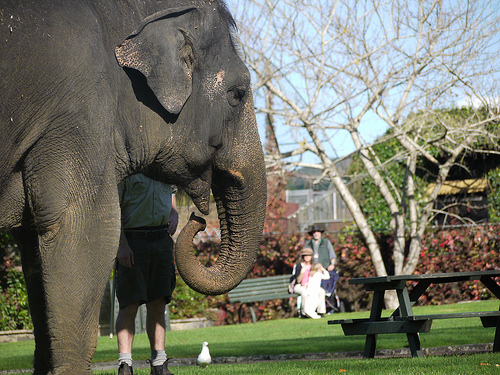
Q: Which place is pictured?
A: It is a park.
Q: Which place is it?
A: It is a park.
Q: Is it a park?
A: Yes, it is a park.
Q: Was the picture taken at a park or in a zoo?
A: It was taken at a park.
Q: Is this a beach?
A: No, it is a park.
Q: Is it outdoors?
A: Yes, it is outdoors.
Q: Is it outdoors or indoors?
A: It is outdoors.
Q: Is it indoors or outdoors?
A: It is outdoors.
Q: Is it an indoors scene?
A: No, it is outdoors.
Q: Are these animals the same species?
A: No, they are birds and elephants.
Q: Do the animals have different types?
A: Yes, they are birds and elephants.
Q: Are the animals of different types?
A: Yes, they are birds and elephants.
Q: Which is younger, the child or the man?
A: The child is younger than the man.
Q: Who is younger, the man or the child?
A: The child is younger than the man.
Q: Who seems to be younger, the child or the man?
A: The child is younger than the man.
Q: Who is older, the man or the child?
A: The man is older than the child.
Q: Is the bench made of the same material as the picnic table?
A: Yes, both the bench and the picnic table are made of wood.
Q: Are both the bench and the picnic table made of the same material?
A: Yes, both the bench and the picnic table are made of wood.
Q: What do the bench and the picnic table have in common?
A: The material, both the bench and the picnic table are wooden.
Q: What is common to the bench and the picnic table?
A: The material, both the bench and the picnic table are wooden.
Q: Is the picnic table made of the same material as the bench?
A: Yes, both the picnic table and the bench are made of wood.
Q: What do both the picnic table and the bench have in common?
A: The material, both the picnic table and the bench are wooden.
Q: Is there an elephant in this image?
A: Yes, there is an elephant.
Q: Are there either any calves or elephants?
A: Yes, there is an elephant.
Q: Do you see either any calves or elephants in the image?
A: Yes, there is an elephant.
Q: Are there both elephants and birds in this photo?
A: Yes, there are both an elephant and birds.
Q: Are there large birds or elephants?
A: Yes, there is a large elephant.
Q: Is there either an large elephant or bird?
A: Yes, there is a large elephant.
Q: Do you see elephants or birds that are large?
A: Yes, the elephant is large.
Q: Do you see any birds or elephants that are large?
A: Yes, the elephant is large.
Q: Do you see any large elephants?
A: Yes, there is a large elephant.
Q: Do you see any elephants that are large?
A: Yes, there is an elephant that is large.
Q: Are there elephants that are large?
A: Yes, there is an elephant that is large.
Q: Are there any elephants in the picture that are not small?
A: Yes, there is a large elephant.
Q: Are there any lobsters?
A: No, there are no lobsters.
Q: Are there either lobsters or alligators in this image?
A: No, there are no lobsters or alligators.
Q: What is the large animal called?
A: The animal is an elephant.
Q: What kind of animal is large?
A: The animal is an elephant.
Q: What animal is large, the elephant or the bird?
A: The elephant is large.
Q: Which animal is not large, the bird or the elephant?
A: The bird is not large.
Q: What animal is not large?
A: The animal is a bird.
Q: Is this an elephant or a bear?
A: This is an elephant.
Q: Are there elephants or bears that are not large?
A: No, there is an elephant but it is large.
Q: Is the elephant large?
A: Yes, the elephant is large.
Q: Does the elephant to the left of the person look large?
A: Yes, the elephant is large.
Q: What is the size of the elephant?
A: The elephant is large.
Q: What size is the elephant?
A: The elephant is large.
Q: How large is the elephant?
A: The elephant is large.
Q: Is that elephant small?
A: No, the elephant is large.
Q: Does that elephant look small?
A: No, the elephant is large.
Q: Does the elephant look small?
A: No, the elephant is large.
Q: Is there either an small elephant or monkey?
A: No, there is an elephant but it is large.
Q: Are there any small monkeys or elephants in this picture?
A: No, there is an elephant but it is large.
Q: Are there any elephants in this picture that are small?
A: No, there is an elephant but it is large.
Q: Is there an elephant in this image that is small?
A: No, there is an elephant but it is large.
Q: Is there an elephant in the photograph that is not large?
A: No, there is an elephant but it is large.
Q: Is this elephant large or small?
A: The elephant is large.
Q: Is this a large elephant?
A: Yes, this is a large elephant.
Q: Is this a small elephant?
A: No, this is a large elephant.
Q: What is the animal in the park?
A: The animal is an elephant.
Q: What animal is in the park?
A: The animal is an elephant.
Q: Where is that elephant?
A: The elephant is in the park.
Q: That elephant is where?
A: The elephant is in the park.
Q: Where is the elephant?
A: The elephant is in the park.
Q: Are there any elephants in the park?
A: Yes, there is an elephant in the park.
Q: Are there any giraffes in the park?
A: No, there is an elephant in the park.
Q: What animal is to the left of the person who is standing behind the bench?
A: The animal is an elephant.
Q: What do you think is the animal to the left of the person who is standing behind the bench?
A: The animal is an elephant.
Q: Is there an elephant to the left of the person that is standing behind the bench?
A: Yes, there is an elephant to the left of the person.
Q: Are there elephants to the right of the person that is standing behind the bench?
A: No, the elephant is to the left of the person.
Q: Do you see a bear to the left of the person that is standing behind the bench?
A: No, there is an elephant to the left of the person.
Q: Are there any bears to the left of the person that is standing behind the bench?
A: No, there is an elephant to the left of the person.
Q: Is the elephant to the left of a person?
A: Yes, the elephant is to the left of a person.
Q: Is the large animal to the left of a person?
A: Yes, the elephant is to the left of a person.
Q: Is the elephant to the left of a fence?
A: No, the elephant is to the left of a person.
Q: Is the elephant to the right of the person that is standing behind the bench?
A: No, the elephant is to the left of the person.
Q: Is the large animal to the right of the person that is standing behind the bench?
A: No, the elephant is to the left of the person.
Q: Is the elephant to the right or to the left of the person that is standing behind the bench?
A: The elephant is to the left of the person.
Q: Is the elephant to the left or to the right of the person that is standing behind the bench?
A: The elephant is to the left of the person.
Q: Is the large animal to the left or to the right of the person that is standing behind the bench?
A: The elephant is to the left of the person.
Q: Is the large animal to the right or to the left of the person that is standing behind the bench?
A: The elephant is to the left of the person.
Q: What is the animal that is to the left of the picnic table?
A: The animal is an elephant.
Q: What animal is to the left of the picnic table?
A: The animal is an elephant.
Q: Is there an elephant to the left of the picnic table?
A: Yes, there is an elephant to the left of the picnic table.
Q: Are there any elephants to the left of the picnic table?
A: Yes, there is an elephant to the left of the picnic table.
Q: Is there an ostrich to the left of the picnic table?
A: No, there is an elephant to the left of the picnic table.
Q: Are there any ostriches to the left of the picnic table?
A: No, there is an elephant to the left of the picnic table.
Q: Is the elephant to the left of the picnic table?
A: Yes, the elephant is to the left of the picnic table.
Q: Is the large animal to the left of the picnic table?
A: Yes, the elephant is to the left of the picnic table.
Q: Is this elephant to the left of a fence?
A: No, the elephant is to the left of the picnic table.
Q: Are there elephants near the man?
A: Yes, there is an elephant near the man.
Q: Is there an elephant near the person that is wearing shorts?
A: Yes, there is an elephant near the man.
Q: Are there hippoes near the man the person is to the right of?
A: No, there is an elephant near the man.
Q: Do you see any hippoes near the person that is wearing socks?
A: No, there is an elephant near the man.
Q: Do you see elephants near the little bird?
A: Yes, there is an elephant near the bird.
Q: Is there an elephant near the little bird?
A: Yes, there is an elephant near the bird.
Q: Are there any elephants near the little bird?
A: Yes, there is an elephant near the bird.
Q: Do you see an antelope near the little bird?
A: No, there is an elephant near the bird.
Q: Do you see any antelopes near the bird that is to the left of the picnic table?
A: No, there is an elephant near the bird.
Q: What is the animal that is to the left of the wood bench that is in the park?
A: The animal is an elephant.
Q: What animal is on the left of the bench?
A: The animal is an elephant.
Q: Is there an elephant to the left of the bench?
A: Yes, there is an elephant to the left of the bench.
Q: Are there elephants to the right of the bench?
A: No, the elephant is to the left of the bench.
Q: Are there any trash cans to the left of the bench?
A: No, there is an elephant to the left of the bench.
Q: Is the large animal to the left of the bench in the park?
A: Yes, the elephant is to the left of the bench.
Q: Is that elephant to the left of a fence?
A: No, the elephant is to the left of the bench.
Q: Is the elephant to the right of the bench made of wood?
A: No, the elephant is to the left of the bench.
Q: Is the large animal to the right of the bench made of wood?
A: No, the elephant is to the left of the bench.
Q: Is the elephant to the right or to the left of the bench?
A: The elephant is to the left of the bench.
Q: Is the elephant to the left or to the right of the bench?
A: The elephant is to the left of the bench.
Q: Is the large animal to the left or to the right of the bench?
A: The elephant is to the left of the bench.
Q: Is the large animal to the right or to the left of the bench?
A: The elephant is to the left of the bench.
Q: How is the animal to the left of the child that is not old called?
A: The animal is an elephant.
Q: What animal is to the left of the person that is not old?
A: The animal is an elephant.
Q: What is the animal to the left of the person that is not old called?
A: The animal is an elephant.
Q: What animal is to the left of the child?
A: The animal is an elephant.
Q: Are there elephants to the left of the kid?
A: Yes, there is an elephant to the left of the kid.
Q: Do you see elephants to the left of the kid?
A: Yes, there is an elephant to the left of the kid.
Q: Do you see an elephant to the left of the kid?
A: Yes, there is an elephant to the left of the kid.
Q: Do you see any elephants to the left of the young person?
A: Yes, there is an elephant to the left of the kid.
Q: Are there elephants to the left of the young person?
A: Yes, there is an elephant to the left of the kid.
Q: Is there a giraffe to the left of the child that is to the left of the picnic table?
A: No, there is an elephant to the left of the child.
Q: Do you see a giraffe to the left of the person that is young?
A: No, there is an elephant to the left of the child.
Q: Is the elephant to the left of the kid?
A: Yes, the elephant is to the left of the kid.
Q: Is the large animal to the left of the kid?
A: Yes, the elephant is to the left of the kid.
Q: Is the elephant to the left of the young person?
A: Yes, the elephant is to the left of the kid.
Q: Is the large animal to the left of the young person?
A: Yes, the elephant is to the left of the kid.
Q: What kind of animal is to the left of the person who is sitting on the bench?
A: The animal is an elephant.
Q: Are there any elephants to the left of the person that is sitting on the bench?
A: Yes, there is an elephant to the left of the person.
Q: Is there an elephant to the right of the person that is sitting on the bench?
A: No, the elephant is to the left of the person.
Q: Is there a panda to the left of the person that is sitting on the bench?
A: No, there is an elephant to the left of the person.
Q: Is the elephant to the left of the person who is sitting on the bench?
A: Yes, the elephant is to the left of the person.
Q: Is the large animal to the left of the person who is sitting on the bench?
A: Yes, the elephant is to the left of the person.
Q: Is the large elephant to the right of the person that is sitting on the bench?
A: No, the elephant is to the left of the person.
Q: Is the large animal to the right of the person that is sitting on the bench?
A: No, the elephant is to the left of the person.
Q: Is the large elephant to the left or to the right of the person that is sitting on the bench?
A: The elephant is to the left of the person.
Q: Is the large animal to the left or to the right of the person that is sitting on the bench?
A: The elephant is to the left of the person.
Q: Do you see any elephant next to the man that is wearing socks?
A: Yes, there is an elephant next to the man.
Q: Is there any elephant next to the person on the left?
A: Yes, there is an elephant next to the man.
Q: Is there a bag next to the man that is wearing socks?
A: No, there is an elephant next to the man.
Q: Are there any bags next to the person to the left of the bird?
A: No, there is an elephant next to the man.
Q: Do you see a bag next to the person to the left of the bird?
A: No, there is an elephant next to the man.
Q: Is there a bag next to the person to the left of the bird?
A: No, there is an elephant next to the man.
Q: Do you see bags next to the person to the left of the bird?
A: No, there is an elephant next to the man.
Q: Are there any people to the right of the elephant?
A: Yes, there is a person to the right of the elephant.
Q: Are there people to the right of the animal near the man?
A: Yes, there is a person to the right of the elephant.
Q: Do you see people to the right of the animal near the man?
A: Yes, there is a person to the right of the elephant.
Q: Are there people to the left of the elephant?
A: No, the person is to the right of the elephant.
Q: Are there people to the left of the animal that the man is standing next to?
A: No, the person is to the right of the elephant.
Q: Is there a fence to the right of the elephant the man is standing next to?
A: No, there is a person to the right of the elephant.